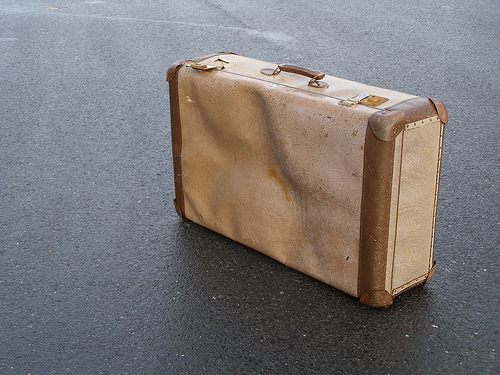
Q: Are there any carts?
A: No, there are no carts.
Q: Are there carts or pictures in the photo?
A: No, there are no carts or pictures.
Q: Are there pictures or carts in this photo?
A: No, there are no carts or pictures.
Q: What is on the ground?
A: The suitcase is on the ground.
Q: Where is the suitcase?
A: The suitcase is on the ground.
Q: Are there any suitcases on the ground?
A: Yes, there is a suitcase on the ground.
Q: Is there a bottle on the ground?
A: No, there is a suitcase on the ground.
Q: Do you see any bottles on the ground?
A: No, there is a suitcase on the ground.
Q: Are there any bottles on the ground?
A: No, there is a suitcase on the ground.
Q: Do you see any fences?
A: No, there are no fences.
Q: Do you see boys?
A: No, there are no boys.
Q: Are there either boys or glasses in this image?
A: No, there are no boys or glasses.